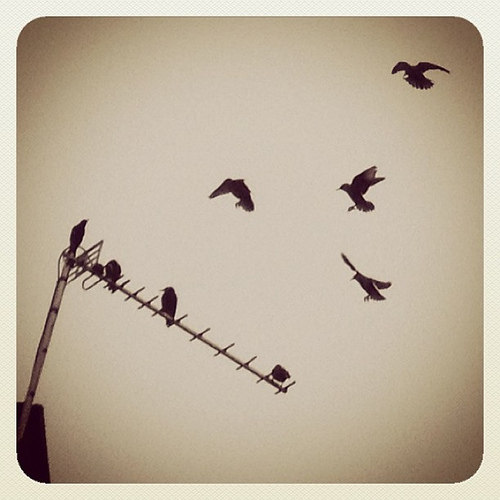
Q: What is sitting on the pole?
A: Birds.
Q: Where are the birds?
A: On the pole.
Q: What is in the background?
A: The sky.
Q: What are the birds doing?
A: Flying to the pole.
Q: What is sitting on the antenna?
A: Birds.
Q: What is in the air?
A: Birds.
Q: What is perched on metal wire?
A: Birds.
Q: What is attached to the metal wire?
A: Pole.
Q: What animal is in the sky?
A: Bird.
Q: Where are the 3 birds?
A: In air.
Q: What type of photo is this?
A: Black and white.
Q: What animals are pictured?
A: Birds.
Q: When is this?
A: Daytime.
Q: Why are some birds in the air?
A: They are flying.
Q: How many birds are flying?
A: Four.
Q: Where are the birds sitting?
A: On the antennae.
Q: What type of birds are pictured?
A: Pigeons.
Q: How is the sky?
A: Overcast.